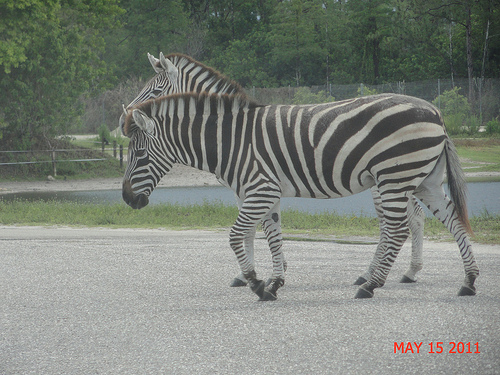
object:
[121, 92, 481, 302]
zebra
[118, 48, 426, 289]
zebra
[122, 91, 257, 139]
mane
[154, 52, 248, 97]
mane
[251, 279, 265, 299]
hoof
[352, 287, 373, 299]
hoof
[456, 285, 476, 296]
hoof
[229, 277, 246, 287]
hoof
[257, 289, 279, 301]
hoof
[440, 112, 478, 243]
tail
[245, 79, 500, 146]
fence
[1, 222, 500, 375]
pavement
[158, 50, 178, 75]
ear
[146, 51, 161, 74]
ear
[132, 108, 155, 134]
ear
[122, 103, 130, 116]
ear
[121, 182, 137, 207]
nose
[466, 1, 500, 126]
trees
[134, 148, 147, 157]
eye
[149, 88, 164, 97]
eye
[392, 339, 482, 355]
date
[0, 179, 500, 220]
water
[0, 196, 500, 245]
grass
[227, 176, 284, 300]
legs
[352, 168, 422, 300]
legs